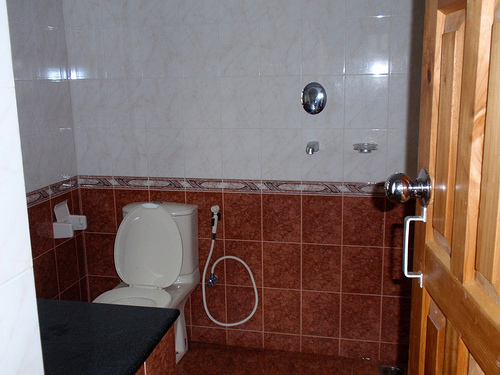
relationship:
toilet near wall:
[95, 208, 206, 307] [0, 0, 411, 188]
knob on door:
[372, 168, 441, 218] [418, 34, 497, 277]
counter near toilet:
[60, 302, 165, 367] [95, 208, 206, 307]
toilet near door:
[95, 208, 206, 307] [418, 34, 497, 277]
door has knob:
[418, 34, 497, 277] [372, 168, 441, 218]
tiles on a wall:
[264, 197, 327, 266] [178, 101, 270, 188]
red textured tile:
[275, 244, 337, 337] [317, 296, 345, 361]